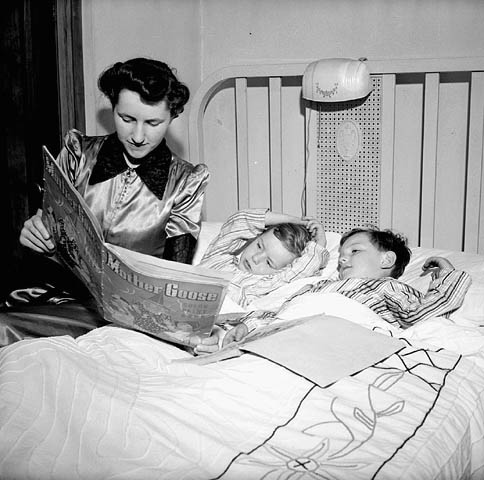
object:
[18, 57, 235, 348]
woman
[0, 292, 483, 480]
blanket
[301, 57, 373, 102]
lamp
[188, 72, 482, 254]
bed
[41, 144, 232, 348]
book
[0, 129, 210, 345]
dress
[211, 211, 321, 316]
shirt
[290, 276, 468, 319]
shirt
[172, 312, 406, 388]
book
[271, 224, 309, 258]
head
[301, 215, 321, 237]
hand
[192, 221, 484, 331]
pillow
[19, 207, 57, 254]
hand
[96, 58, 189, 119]
hair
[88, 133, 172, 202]
collar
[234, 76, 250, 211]
rail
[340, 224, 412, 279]
hair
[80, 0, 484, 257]
wall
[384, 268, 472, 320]
arm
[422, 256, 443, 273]
hand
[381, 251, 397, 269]
ear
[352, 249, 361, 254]
eye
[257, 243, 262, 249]
eye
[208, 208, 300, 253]
arm